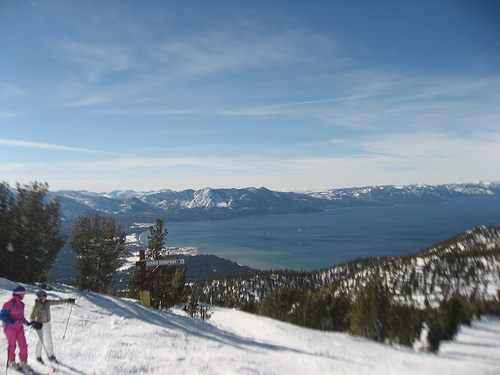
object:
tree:
[145, 219, 169, 259]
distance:
[79, 184, 264, 229]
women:
[2, 283, 30, 361]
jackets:
[31, 300, 51, 324]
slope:
[68, 286, 442, 374]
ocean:
[205, 207, 441, 260]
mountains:
[139, 186, 303, 221]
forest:
[331, 269, 463, 334]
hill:
[412, 233, 500, 280]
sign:
[137, 258, 187, 266]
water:
[225, 215, 306, 259]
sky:
[0, 6, 499, 155]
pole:
[139, 271, 148, 307]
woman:
[33, 288, 82, 360]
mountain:
[0, 226, 499, 372]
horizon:
[8, 171, 493, 224]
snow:
[184, 189, 211, 203]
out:
[198, 185, 489, 296]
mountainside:
[126, 239, 424, 372]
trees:
[350, 275, 401, 341]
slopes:
[174, 242, 476, 350]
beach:
[183, 247, 273, 281]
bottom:
[139, 250, 228, 286]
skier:
[1, 286, 39, 371]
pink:
[1, 300, 28, 355]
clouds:
[68, 84, 265, 163]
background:
[0, 0, 497, 269]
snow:
[123, 319, 224, 350]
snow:
[396, 267, 414, 299]